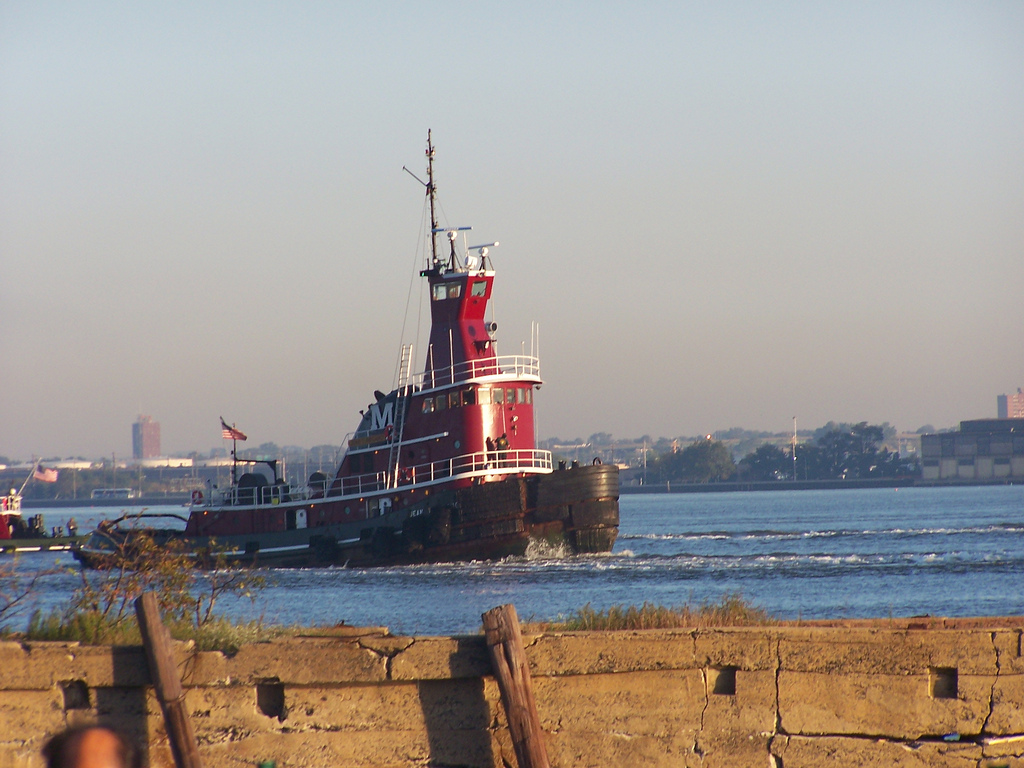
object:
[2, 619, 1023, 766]
wall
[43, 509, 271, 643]
tree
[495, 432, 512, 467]
man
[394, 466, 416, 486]
man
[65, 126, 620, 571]
boat